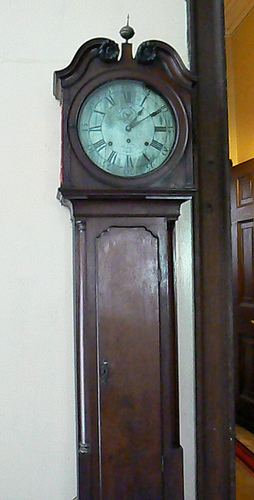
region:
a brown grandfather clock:
[52, 17, 195, 498]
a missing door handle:
[99, 358, 110, 383]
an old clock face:
[70, 71, 189, 184]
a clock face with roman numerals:
[64, 66, 188, 185]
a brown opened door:
[226, 157, 252, 432]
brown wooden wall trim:
[184, 1, 235, 498]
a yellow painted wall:
[223, 8, 253, 166]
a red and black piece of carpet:
[233, 437, 253, 471]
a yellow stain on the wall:
[1, 56, 70, 66]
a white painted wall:
[1, 1, 186, 12]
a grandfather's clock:
[43, 11, 194, 497]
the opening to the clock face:
[65, 65, 184, 184]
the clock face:
[76, 76, 171, 172]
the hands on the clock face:
[127, 103, 161, 126]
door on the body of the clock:
[90, 223, 155, 494]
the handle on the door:
[98, 356, 105, 381]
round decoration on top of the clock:
[117, 12, 131, 38]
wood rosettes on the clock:
[95, 37, 152, 57]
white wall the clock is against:
[0, 0, 192, 497]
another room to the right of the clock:
[224, 0, 250, 497]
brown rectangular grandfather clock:
[51, 11, 193, 499]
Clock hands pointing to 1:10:
[118, 101, 166, 129]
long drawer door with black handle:
[82, 218, 165, 495]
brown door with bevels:
[229, 156, 248, 429]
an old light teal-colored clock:
[60, 60, 183, 181]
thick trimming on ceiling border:
[222, 0, 249, 39]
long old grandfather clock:
[51, 2, 194, 497]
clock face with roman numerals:
[61, 64, 189, 188]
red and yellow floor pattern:
[234, 423, 253, 498]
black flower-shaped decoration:
[97, 38, 120, 61]